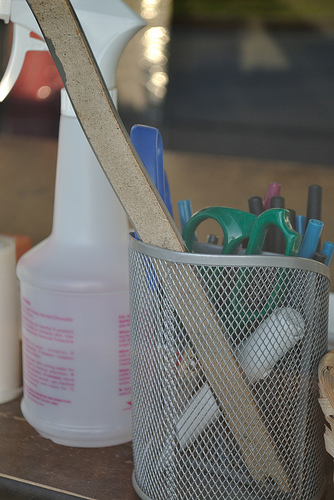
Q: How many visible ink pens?
A: Eleven.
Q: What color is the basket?
A: Grey.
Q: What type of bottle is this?
A: Spray bottle.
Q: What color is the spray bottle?
A: White.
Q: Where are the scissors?
A: In basket.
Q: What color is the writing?
A: Pink.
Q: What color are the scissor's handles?
A: Green.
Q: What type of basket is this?
A: Mesh.